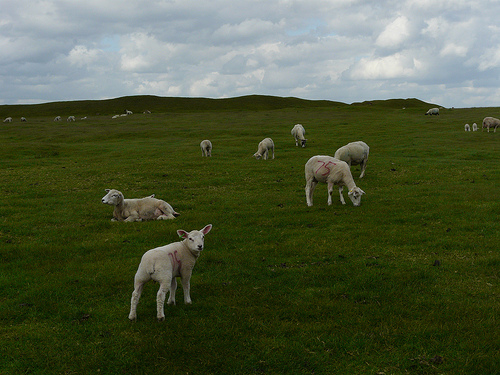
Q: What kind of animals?
A: Sheep.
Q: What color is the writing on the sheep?
A: Red.